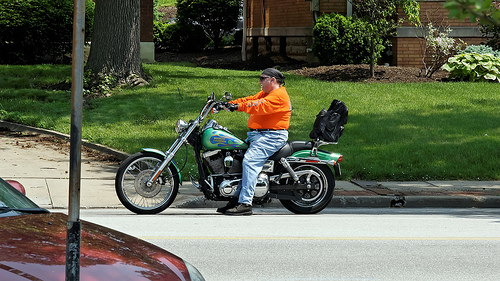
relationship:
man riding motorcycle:
[230, 59, 292, 191] [122, 93, 339, 215]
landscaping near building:
[186, 32, 500, 83] [243, 0, 500, 70]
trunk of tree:
[86, 0, 150, 91] [87, 0, 154, 72]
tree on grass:
[87, 0, 154, 72] [0, 64, 500, 181]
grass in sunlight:
[0, 64, 500, 181] [6, 3, 491, 276]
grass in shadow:
[0, 64, 500, 181] [102, 80, 200, 116]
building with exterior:
[244, 3, 495, 63] [243, 1, 495, 76]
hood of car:
[2, 215, 182, 275] [4, 176, 195, 279]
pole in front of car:
[67, 2, 90, 280] [4, 176, 195, 279]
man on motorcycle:
[230, 59, 292, 191] [122, 93, 339, 215]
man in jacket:
[230, 59, 292, 191] [228, 86, 292, 130]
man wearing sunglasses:
[230, 59, 292, 191] [255, 74, 272, 79]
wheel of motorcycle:
[111, 149, 179, 214] [122, 93, 339, 215]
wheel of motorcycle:
[277, 160, 343, 211] [122, 93, 339, 215]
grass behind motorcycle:
[23, 63, 496, 181] [122, 93, 339, 215]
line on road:
[140, 229, 493, 244] [30, 208, 499, 275]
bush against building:
[314, 16, 370, 63] [243, 0, 500, 70]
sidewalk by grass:
[22, 172, 494, 205] [23, 63, 496, 181]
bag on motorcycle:
[314, 96, 353, 145] [122, 93, 339, 215]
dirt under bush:
[288, 62, 436, 85] [314, 16, 370, 63]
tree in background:
[87, 0, 154, 72] [7, 2, 497, 101]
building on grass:
[244, 3, 495, 63] [23, 63, 496, 181]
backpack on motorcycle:
[314, 96, 353, 145] [122, 93, 339, 215]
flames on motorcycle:
[214, 128, 244, 150] [122, 93, 339, 215]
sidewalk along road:
[22, 172, 494, 205] [44, 208, 499, 281]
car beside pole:
[4, 176, 195, 279] [67, 2, 90, 280]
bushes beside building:
[169, 2, 247, 63] [244, 3, 495, 63]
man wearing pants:
[230, 59, 292, 191] [241, 129, 286, 201]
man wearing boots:
[230, 59, 292, 191] [220, 192, 254, 218]